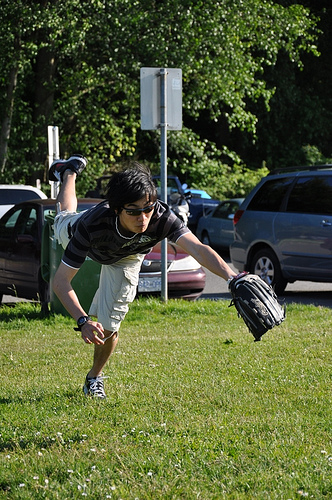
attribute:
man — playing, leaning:
[45, 154, 283, 398]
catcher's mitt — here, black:
[227, 269, 285, 342]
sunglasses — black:
[121, 204, 154, 217]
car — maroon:
[1, 199, 205, 303]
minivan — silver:
[229, 166, 331, 293]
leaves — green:
[1, 0, 331, 201]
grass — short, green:
[1, 299, 331, 499]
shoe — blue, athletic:
[44, 155, 86, 182]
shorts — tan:
[54, 210, 147, 335]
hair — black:
[106, 167, 155, 218]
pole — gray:
[158, 67, 168, 303]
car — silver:
[195, 197, 245, 252]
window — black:
[245, 175, 331, 215]